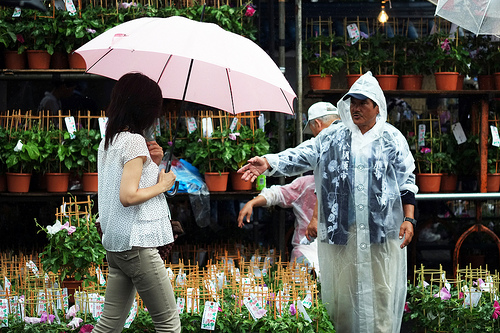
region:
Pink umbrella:
[96, 18, 309, 115]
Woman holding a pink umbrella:
[90, 45, 196, 330]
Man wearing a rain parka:
[310, 56, 417, 318]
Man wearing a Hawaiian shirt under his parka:
[296, 112, 431, 254]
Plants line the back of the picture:
[297, 12, 481, 96]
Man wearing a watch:
[392, 200, 426, 250]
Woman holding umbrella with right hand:
[152, 161, 185, 202]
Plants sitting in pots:
[5, 160, 76, 194]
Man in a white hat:
[292, 95, 341, 130]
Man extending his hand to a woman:
[205, 147, 331, 174]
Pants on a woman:
[86, 234, 198, 330]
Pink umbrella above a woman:
[66, 2, 332, 121]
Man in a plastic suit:
[270, 56, 442, 330]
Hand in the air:
[223, 138, 272, 182]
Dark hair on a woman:
[97, 71, 177, 161]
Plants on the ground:
[27, 216, 369, 331]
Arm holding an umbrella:
[121, 145, 178, 237]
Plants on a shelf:
[13, 98, 233, 201]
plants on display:
[305, 8, 475, 105]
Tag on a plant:
[196, 289, 226, 331]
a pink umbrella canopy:
[72, 16, 295, 115]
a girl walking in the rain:
[75, 15, 295, 332]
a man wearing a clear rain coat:
[237, 70, 414, 331]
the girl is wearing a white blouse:
[95, 130, 170, 245]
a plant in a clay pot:
[413, 113, 442, 192]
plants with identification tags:
[200, 281, 222, 332]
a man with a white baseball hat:
[302, 100, 338, 133]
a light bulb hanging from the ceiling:
[375, 0, 390, 26]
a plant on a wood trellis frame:
[42, 195, 102, 302]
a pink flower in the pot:
[39, 308, 55, 325]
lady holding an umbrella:
[27, 1, 329, 331]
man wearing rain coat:
[252, 35, 480, 321]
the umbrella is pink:
[74, 11, 335, 175]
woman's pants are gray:
[86, 229, 207, 329]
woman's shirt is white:
[67, 113, 183, 245]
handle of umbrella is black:
[164, 51, 199, 236]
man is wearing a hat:
[337, 72, 374, 111]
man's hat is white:
[290, 92, 343, 139]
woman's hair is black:
[97, 66, 167, 137]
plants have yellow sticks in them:
[165, 251, 337, 321]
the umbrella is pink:
[56, 16, 413, 252]